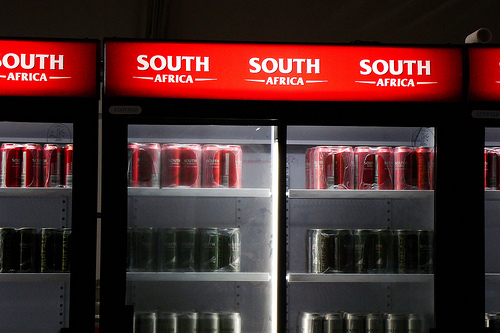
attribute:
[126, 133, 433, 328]
drinks — black, fridge, glass, displayed, assorted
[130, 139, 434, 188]
cans — red, reddish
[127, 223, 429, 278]
cans — green, soda, wrapped in plastic, gold, black, blackish, drink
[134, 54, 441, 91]
lettering — white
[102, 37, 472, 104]
background — red, white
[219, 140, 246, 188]
can — red, silver, from a can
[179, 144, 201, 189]
can — red, silver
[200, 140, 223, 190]
can — red, silver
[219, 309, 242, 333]
can — black, silver, white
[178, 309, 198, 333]
can — black, silver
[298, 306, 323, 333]
can — black, silver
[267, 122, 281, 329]
tube — light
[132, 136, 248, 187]
light — reflecting, from a wrapper, opened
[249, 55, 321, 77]
word — in white, south